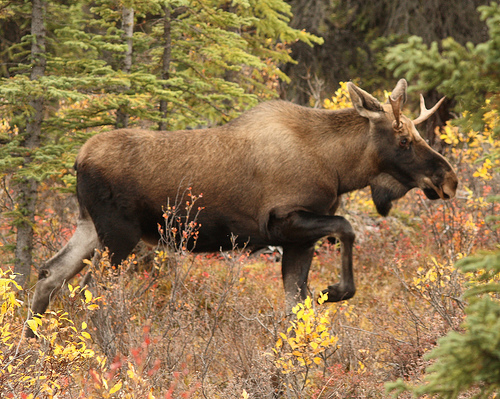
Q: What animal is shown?
A: Moose.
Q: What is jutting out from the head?
A: Antlers.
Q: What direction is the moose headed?
A: To the right.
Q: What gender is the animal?
A: Male.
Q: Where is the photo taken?
A: A forest.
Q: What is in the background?
A: Trees.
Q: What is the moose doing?
A: Running.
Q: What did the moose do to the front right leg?
A: It is bent.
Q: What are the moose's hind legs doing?
A: Moving.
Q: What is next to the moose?
A: Yellow plants.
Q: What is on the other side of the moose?
A: Green pine trees.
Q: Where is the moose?
A: In the bushes.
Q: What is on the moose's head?
A: Horns.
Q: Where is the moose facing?
A: Right.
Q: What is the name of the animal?
A: A moose.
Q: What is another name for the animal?
A: An elk.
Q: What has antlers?
A: The elk.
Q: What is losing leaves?
A: The branches.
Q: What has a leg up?
A: The elk.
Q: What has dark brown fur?
A: The elk.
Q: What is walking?
A: The moose.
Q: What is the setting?
A: A forest.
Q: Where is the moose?
A: In the forest.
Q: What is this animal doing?
A: Running.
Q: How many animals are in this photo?
A: One.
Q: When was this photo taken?
A: Outside, during the daytime.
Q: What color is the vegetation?
A: Green and yellow.